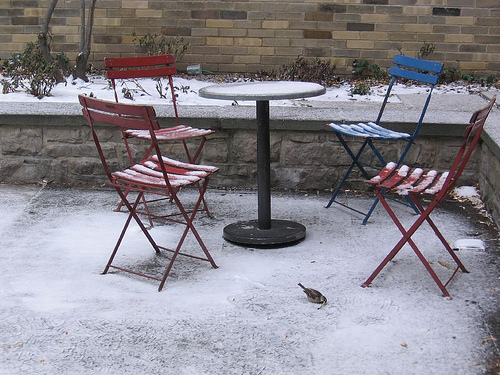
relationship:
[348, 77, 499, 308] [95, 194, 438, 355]
chair in snow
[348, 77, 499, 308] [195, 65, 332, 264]
chair on table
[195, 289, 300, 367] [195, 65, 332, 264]
snow covering table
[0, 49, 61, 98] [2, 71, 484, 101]
bush protruding through snow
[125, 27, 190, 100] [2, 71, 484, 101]
bush protruding through snow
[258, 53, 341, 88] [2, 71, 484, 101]
bush protruding through snow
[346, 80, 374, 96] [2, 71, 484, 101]
bush protruding through snow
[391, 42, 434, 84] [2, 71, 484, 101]
bush protruding through snow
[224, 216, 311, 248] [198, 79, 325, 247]
base supporting table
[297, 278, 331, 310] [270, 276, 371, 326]
bird on ground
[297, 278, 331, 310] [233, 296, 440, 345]
bird standing in snow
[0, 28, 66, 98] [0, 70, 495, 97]
bush in flower bed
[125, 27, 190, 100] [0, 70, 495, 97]
bush in flower bed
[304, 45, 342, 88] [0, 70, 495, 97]
bush in flower bed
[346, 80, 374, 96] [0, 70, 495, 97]
bush in flower bed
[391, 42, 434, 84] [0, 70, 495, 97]
bush in flower bed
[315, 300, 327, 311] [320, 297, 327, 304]
twig in mouth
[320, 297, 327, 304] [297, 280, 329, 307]
mouth on bird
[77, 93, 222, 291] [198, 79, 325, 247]
chair are by table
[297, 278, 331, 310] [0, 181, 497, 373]
bird on ground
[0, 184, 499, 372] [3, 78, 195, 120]
snow on ledge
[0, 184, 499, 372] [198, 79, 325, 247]
snow on table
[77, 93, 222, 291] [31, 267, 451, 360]
chair in snow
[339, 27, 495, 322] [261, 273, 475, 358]
chair in snow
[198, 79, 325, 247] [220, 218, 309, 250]
table on base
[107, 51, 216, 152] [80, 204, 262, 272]
chair on snow